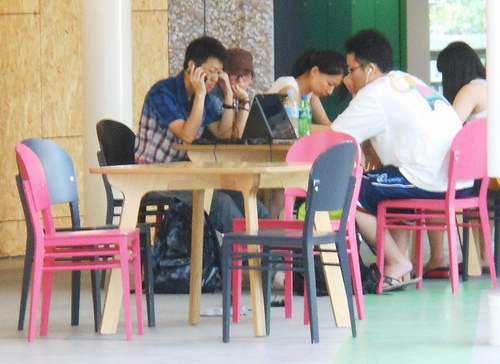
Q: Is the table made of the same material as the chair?
A: No, the table is made of wood and the chair is made of metal.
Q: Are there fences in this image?
A: No, there are no fences.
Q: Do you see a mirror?
A: No, there are no mirrors.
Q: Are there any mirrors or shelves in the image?
A: No, there are no mirrors or shelves.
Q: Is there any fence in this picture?
A: No, there are no fences.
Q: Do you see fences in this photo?
A: No, there are no fences.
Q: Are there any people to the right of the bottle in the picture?
A: Yes, there is a person to the right of the bottle.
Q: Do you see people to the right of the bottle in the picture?
A: Yes, there is a person to the right of the bottle.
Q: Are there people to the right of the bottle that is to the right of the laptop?
A: Yes, there is a person to the right of the bottle.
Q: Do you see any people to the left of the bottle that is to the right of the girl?
A: No, the person is to the right of the bottle.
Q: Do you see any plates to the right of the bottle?
A: No, there is a person to the right of the bottle.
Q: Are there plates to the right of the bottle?
A: No, there is a person to the right of the bottle.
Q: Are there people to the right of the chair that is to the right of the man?
A: Yes, there is a person to the right of the chair.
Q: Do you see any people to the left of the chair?
A: No, the person is to the right of the chair.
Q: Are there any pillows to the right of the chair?
A: No, there is a person to the right of the chair.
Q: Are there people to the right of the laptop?
A: Yes, there is a person to the right of the laptop.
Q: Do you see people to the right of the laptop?
A: Yes, there is a person to the right of the laptop.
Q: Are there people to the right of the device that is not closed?
A: Yes, there is a person to the right of the laptop.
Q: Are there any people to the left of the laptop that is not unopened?
A: No, the person is to the right of the laptop.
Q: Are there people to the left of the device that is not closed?
A: No, the person is to the right of the laptop.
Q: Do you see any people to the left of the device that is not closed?
A: No, the person is to the right of the laptop.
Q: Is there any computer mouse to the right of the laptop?
A: No, there is a person to the right of the laptop.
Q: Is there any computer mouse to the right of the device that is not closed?
A: No, there is a person to the right of the laptop.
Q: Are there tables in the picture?
A: Yes, there is a table.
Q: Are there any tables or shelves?
A: Yes, there is a table.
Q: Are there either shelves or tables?
A: Yes, there is a table.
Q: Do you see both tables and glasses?
A: Yes, there are both a table and glasses.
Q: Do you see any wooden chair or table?
A: Yes, there is a wood table.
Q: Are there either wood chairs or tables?
A: Yes, there is a wood table.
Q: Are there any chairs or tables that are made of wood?
A: Yes, the table is made of wood.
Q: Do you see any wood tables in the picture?
A: Yes, there is a wood table.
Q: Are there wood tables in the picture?
A: Yes, there is a wood table.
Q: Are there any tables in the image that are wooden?
A: Yes, there is a table that is wooden.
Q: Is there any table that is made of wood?
A: Yes, there is a table that is made of wood.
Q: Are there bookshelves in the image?
A: No, there are no bookshelves.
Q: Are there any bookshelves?
A: No, there are no bookshelves.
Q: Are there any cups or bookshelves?
A: No, there are no bookshelves or cups.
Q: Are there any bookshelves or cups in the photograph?
A: No, there are no bookshelves or cups.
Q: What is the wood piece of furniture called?
A: The piece of furniture is a table.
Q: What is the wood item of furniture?
A: The piece of furniture is a table.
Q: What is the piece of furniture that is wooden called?
A: The piece of furniture is a table.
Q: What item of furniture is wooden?
A: The piece of furniture is a table.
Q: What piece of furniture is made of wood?
A: The piece of furniture is a table.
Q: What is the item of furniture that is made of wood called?
A: The piece of furniture is a table.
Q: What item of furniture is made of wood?
A: The piece of furniture is a table.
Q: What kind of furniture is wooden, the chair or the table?
A: The table is wooden.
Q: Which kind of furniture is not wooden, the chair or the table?
A: The chair is not wooden.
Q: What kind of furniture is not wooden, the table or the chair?
A: The chair is not wooden.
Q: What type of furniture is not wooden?
A: The furniture is a chair.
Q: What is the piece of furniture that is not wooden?
A: The piece of furniture is a chair.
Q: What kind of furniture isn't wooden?
A: The furniture is a chair.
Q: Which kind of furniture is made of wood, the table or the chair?
A: The table is made of wood.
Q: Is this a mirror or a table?
A: This is a table.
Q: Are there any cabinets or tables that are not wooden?
A: No, there is a table but it is wooden.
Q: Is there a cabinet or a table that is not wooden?
A: No, there is a table but it is wooden.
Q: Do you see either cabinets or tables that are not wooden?
A: No, there is a table but it is wooden.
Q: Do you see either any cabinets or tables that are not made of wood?
A: No, there is a table but it is made of wood.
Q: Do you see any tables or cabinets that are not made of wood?
A: No, there is a table but it is made of wood.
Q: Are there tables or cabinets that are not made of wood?
A: No, there is a table but it is made of wood.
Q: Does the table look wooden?
A: Yes, the table is wooden.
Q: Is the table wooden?
A: Yes, the table is wooden.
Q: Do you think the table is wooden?
A: Yes, the table is wooden.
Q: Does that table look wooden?
A: Yes, the table is wooden.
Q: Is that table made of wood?
A: Yes, the table is made of wood.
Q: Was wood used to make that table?
A: Yes, the table is made of wood.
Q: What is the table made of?
A: The table is made of wood.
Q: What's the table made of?
A: The table is made of wood.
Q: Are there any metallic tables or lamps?
A: No, there is a table but it is wooden.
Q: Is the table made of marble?
A: No, the table is made of wood.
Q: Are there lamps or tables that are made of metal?
A: No, there is a table but it is made of wood.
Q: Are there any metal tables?
A: No, there is a table but it is made of wood.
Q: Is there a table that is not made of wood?
A: No, there is a table but it is made of wood.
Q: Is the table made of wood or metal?
A: The table is made of wood.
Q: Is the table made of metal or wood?
A: The table is made of wood.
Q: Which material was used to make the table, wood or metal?
A: The table is made of wood.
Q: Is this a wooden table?
A: Yes, this is a wooden table.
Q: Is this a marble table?
A: No, this is a wooden table.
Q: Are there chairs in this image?
A: Yes, there is a chair.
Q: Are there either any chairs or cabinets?
A: Yes, there is a chair.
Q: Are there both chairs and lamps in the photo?
A: No, there is a chair but no lamps.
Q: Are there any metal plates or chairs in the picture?
A: Yes, there is a metal chair.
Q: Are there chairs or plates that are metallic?
A: Yes, the chair is metallic.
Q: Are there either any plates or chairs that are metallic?
A: Yes, the chair is metallic.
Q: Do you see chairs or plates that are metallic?
A: Yes, the chair is metallic.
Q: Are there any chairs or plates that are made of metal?
A: Yes, the chair is made of metal.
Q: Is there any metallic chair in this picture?
A: Yes, there is a metal chair.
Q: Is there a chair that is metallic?
A: Yes, there is a chair that is metallic.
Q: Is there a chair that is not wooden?
A: Yes, there is a metallic chair.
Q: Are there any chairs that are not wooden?
A: Yes, there is a metallic chair.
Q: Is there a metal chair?
A: Yes, there is a chair that is made of metal.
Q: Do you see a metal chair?
A: Yes, there is a chair that is made of metal.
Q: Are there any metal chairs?
A: Yes, there is a chair that is made of metal.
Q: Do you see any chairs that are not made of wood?
A: Yes, there is a chair that is made of metal.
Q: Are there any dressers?
A: No, there are no dressers.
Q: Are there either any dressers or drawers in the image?
A: No, there are no dressers or drawers.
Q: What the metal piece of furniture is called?
A: The piece of furniture is a chair.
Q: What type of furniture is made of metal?
A: The furniture is a chair.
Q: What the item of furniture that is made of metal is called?
A: The piece of furniture is a chair.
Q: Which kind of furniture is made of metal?
A: The furniture is a chair.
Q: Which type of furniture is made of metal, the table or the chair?
A: The chair is made of metal.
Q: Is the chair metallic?
A: Yes, the chair is metallic.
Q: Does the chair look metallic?
A: Yes, the chair is metallic.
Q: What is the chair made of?
A: The chair is made of metal.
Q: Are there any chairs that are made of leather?
A: No, there is a chair but it is made of metal.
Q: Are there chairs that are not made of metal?
A: No, there is a chair but it is made of metal.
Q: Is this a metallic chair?
A: Yes, this is a metallic chair.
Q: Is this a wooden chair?
A: No, this is a metallic chair.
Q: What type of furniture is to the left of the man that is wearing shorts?
A: The piece of furniture is a chair.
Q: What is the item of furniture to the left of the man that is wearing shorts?
A: The piece of furniture is a chair.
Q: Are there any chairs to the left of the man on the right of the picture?
A: Yes, there is a chair to the left of the man.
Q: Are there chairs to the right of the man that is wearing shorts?
A: No, the chair is to the left of the man.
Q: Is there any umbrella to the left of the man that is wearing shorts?
A: No, there is a chair to the left of the man.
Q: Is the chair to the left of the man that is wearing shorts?
A: Yes, the chair is to the left of the man.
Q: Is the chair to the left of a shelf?
A: No, the chair is to the left of the man.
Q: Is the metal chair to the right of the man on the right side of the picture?
A: No, the chair is to the left of the man.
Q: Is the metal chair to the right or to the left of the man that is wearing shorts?
A: The chair is to the left of the man.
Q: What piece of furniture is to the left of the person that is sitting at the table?
A: The piece of furniture is a chair.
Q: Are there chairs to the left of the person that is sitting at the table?
A: Yes, there is a chair to the left of the person.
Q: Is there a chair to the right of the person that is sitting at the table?
A: No, the chair is to the left of the person.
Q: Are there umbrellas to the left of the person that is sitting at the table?
A: No, there is a chair to the left of the person.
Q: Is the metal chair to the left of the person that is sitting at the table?
A: Yes, the chair is to the left of the person.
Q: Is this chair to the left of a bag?
A: No, the chair is to the left of the person.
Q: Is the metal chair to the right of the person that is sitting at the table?
A: No, the chair is to the left of the person.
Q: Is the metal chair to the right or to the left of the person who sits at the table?
A: The chair is to the left of the person.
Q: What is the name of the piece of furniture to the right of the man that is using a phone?
A: The piece of furniture is a chair.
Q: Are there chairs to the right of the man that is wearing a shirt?
A: Yes, there is a chair to the right of the man.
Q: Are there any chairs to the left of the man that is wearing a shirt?
A: No, the chair is to the right of the man.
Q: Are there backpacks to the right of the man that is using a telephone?
A: No, there is a chair to the right of the man.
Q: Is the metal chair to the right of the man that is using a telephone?
A: Yes, the chair is to the right of the man.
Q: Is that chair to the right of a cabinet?
A: No, the chair is to the right of the man.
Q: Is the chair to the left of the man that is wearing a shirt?
A: No, the chair is to the right of the man.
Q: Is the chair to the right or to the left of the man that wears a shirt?
A: The chair is to the right of the man.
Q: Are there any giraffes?
A: No, there are no giraffes.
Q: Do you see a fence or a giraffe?
A: No, there are no giraffes or fences.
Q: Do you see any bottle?
A: Yes, there is a bottle.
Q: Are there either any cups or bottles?
A: Yes, there is a bottle.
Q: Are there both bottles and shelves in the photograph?
A: No, there is a bottle but no shelves.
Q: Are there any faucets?
A: No, there are no faucets.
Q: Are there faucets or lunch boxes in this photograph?
A: No, there are no faucets or lunch boxes.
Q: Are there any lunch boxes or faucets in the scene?
A: No, there are no faucets or lunch boxes.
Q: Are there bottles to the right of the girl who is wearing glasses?
A: Yes, there is a bottle to the right of the girl.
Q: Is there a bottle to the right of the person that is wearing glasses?
A: Yes, there is a bottle to the right of the girl.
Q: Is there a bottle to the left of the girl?
A: No, the bottle is to the right of the girl.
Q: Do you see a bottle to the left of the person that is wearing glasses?
A: No, the bottle is to the right of the girl.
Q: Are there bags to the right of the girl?
A: No, there is a bottle to the right of the girl.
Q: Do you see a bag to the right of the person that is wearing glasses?
A: No, there is a bottle to the right of the girl.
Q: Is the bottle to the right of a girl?
A: Yes, the bottle is to the right of a girl.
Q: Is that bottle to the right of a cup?
A: No, the bottle is to the right of a girl.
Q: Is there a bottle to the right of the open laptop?
A: Yes, there is a bottle to the right of the laptop.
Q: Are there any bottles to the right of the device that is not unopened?
A: Yes, there is a bottle to the right of the laptop.